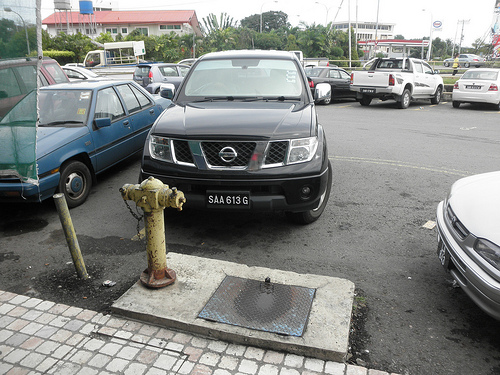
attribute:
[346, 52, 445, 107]
truck — White 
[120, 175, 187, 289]
hydrant — yellow 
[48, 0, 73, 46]
water tank — gray 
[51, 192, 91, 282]
rod — metal, protruding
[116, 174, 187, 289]
fire hydrant — yellow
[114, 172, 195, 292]
fire hydrant — Yellow 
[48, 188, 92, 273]
metal rod — yellow, protruding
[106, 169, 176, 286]
hydrant — yellow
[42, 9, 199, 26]
roof — red 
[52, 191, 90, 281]
pole — yellow 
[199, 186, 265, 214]
license plate — black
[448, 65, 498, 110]
sedan — White 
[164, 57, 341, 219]
car — white 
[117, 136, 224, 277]
pole — tilting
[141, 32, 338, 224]
suv — black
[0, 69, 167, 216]
vehicle — blue 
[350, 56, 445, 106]
truck — white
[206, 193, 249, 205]
lettering — white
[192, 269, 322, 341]
drain cover — metal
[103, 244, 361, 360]
slab — concrete